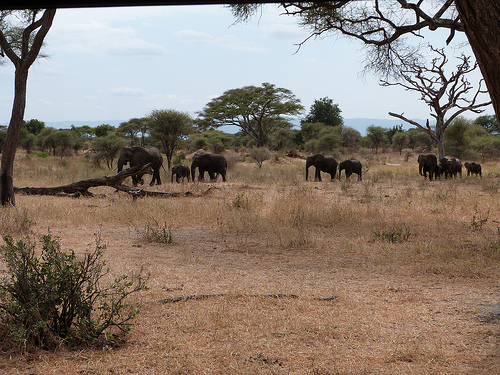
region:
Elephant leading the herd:
[117, 143, 164, 186]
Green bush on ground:
[1, 235, 144, 349]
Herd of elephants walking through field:
[117, 144, 484, 181]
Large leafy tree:
[196, 82, 303, 149]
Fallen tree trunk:
[12, 165, 193, 200]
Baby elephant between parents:
[170, 165, 192, 183]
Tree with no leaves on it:
[387, 50, 492, 177]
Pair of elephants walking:
[304, 151, 364, 181]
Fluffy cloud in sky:
[173, 27, 266, 59]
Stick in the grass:
[146, 292, 337, 302]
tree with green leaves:
[216, 82, 298, 168]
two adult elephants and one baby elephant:
[99, 133, 238, 217]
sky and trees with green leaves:
[49, 78, 360, 143]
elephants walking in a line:
[112, 131, 487, 208]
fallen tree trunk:
[19, 166, 166, 215]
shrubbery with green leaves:
[11, 220, 148, 367]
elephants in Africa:
[12, 71, 477, 355]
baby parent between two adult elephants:
[88, 115, 247, 210]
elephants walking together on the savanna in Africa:
[22, 76, 479, 350]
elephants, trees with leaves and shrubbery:
[12, 71, 492, 314]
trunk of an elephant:
[302, 164, 311, 184]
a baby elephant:
[163, 160, 195, 188]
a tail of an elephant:
[157, 162, 170, 177]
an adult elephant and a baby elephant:
[296, 147, 372, 187]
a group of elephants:
[407, 141, 488, 186]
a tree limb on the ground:
[26, 168, 211, 201]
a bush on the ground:
[0, 213, 140, 364]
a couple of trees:
[200, 81, 297, 148]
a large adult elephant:
[115, 138, 165, 188]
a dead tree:
[401, 67, 475, 132]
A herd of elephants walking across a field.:
[90, 134, 494, 186]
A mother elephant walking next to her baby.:
[186, 151, 236, 185]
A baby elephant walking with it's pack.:
[464, 157, 482, 177]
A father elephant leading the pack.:
[112, 134, 172, 204]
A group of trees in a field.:
[117, 82, 232, 139]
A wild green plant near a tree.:
[0, 207, 186, 367]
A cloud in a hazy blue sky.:
[97, 19, 178, 60]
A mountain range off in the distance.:
[339, 99, 441, 141]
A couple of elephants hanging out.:
[289, 147, 371, 191]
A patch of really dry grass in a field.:
[266, 248, 346, 314]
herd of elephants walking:
[94, 119, 488, 193]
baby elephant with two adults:
[119, 130, 234, 204]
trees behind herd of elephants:
[4, 86, 490, 188]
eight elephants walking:
[96, 137, 498, 202]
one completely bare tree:
[381, 42, 496, 174]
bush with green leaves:
[4, 219, 159, 370]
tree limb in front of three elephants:
[24, 140, 232, 210]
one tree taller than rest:
[22, 77, 497, 181]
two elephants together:
[282, 137, 385, 198]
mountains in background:
[179, 99, 479, 193]